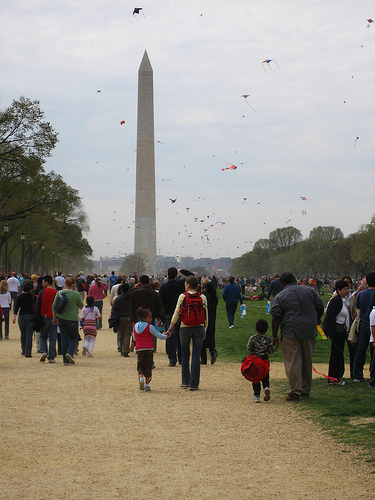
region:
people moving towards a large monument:
[2, 48, 368, 425]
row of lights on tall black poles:
[0, 221, 84, 296]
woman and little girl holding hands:
[127, 269, 219, 397]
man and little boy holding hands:
[240, 269, 325, 409]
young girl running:
[76, 287, 104, 363]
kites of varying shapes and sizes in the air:
[84, 1, 374, 256]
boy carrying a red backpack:
[240, 312, 280, 403]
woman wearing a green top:
[50, 275, 83, 325]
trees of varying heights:
[227, 218, 373, 287]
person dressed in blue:
[217, 273, 248, 329]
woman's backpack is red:
[180, 291, 208, 326]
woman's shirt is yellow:
[166, 289, 224, 338]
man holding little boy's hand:
[226, 249, 328, 412]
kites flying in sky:
[85, 81, 366, 289]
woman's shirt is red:
[43, 285, 83, 330]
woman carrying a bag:
[39, 283, 78, 321]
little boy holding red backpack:
[230, 341, 287, 392]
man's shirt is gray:
[255, 282, 337, 353]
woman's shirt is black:
[12, 292, 39, 309]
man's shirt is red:
[36, 283, 61, 322]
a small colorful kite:
[257, 56, 280, 72]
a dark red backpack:
[240, 356, 271, 382]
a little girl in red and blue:
[129, 305, 171, 391]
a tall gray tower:
[136, 49, 157, 276]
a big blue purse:
[50, 291, 68, 315]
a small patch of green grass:
[267, 378, 374, 458]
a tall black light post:
[16, 229, 28, 275]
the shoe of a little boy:
[258, 388, 273, 401]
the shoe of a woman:
[64, 349, 76, 365]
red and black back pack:
[233, 356, 280, 408]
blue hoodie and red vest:
[124, 321, 171, 362]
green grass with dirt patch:
[330, 387, 373, 470]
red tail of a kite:
[311, 351, 335, 399]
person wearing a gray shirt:
[268, 265, 321, 343]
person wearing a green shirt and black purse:
[45, 275, 78, 328]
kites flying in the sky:
[167, 152, 252, 231]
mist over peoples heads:
[71, 242, 233, 285]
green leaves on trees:
[189, 217, 365, 290]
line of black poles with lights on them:
[0, 219, 95, 275]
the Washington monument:
[130, 42, 160, 275]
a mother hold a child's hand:
[126, 267, 207, 394]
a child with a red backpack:
[238, 314, 277, 401]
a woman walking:
[49, 275, 80, 366]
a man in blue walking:
[221, 274, 247, 329]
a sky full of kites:
[9, 3, 370, 253]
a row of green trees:
[0, 93, 101, 273]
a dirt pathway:
[0, 282, 358, 492]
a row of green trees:
[229, 217, 372, 282]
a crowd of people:
[0, 268, 372, 403]